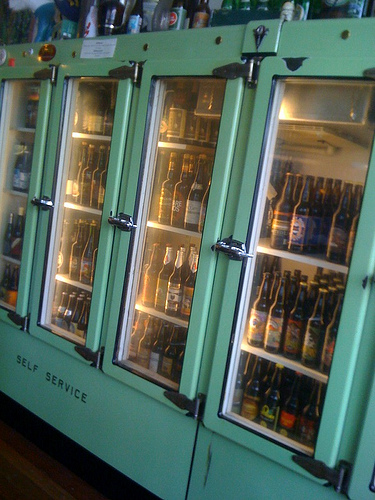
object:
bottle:
[289, 173, 315, 252]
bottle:
[325, 184, 350, 261]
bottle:
[246, 273, 273, 348]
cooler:
[0, 17, 373, 498]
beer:
[295, 377, 321, 445]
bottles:
[265, 273, 291, 355]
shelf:
[257, 236, 349, 275]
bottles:
[347, 0, 363, 14]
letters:
[82, 393, 89, 405]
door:
[101, 72, 246, 421]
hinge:
[246, 58, 255, 85]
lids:
[350, 184, 361, 193]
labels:
[272, 213, 293, 236]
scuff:
[200, 438, 218, 490]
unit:
[271, 82, 372, 151]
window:
[40, 76, 129, 343]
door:
[202, 54, 373, 483]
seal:
[38, 44, 59, 62]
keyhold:
[110, 209, 115, 218]